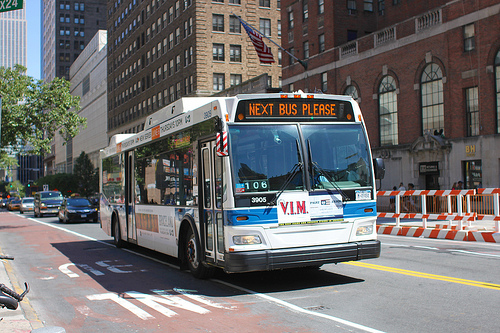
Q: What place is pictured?
A: It is a street.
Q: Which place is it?
A: It is a street.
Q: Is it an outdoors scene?
A: Yes, it is outdoors.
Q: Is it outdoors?
A: Yes, it is outdoors.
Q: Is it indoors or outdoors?
A: It is outdoors.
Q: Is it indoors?
A: No, it is outdoors.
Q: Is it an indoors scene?
A: No, it is outdoors.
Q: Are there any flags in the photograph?
A: Yes, there is a flag.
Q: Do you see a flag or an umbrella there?
A: Yes, there is a flag.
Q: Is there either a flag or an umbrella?
A: Yes, there is a flag.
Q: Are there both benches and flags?
A: No, there is a flag but no benches.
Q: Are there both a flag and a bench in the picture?
A: No, there is a flag but no benches.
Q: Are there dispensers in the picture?
A: No, there are no dispensers.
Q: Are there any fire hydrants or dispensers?
A: No, there are no dispensers or fire hydrants.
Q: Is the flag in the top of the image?
A: Yes, the flag is in the top of the image.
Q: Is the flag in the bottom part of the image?
A: No, the flag is in the top of the image.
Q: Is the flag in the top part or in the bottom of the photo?
A: The flag is in the top of the image.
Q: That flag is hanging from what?
A: The flag is hanging from the building.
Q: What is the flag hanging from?
A: The flag is hanging from the building.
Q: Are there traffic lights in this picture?
A: No, there are no traffic lights.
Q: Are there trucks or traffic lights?
A: No, there are no traffic lights or trucks.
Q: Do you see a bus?
A: Yes, there is a bus.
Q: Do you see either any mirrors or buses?
A: Yes, there is a bus.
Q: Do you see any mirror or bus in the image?
A: Yes, there is a bus.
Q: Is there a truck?
A: No, there are no trucks.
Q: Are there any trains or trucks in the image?
A: No, there are no trucks or trains.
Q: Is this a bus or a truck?
A: This is a bus.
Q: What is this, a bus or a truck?
A: This is a bus.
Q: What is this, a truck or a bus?
A: This is a bus.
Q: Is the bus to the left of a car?
A: No, the bus is to the right of a car.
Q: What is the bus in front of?
A: The bus is in front of the car.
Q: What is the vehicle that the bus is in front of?
A: The vehicle is a car.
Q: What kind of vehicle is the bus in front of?
A: The bus is in front of the car.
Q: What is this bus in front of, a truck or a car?
A: The bus is in front of a car.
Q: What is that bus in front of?
A: The bus is in front of the car.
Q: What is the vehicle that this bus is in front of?
A: The vehicle is a car.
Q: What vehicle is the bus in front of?
A: The bus is in front of the car.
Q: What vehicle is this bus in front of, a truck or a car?
A: The bus is in front of a car.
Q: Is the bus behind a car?
A: No, the bus is in front of a car.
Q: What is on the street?
A: The bus is on the street.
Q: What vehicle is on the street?
A: The vehicle is a bus.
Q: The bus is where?
A: The bus is on the street.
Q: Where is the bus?
A: The bus is on the street.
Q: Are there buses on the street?
A: Yes, there is a bus on the street.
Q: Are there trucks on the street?
A: No, there is a bus on the street.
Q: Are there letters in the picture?
A: Yes, there are letters.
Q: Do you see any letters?
A: Yes, there are letters.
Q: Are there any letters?
A: Yes, there are letters.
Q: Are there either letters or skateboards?
A: Yes, there are letters.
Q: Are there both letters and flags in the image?
A: Yes, there are both letters and flags.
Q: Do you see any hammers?
A: No, there are no hammers.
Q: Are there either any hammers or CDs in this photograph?
A: No, there are no hammers or cds.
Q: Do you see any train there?
A: No, there are no trains.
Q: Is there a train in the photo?
A: No, there are no trains.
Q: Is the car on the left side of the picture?
A: Yes, the car is on the left of the image.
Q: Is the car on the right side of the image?
A: No, the car is on the left of the image.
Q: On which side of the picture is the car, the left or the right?
A: The car is on the left of the image.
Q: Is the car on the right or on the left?
A: The car is on the left of the image.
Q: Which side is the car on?
A: The car is on the left of the image.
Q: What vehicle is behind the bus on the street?
A: The vehicle is a car.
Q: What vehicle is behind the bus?
A: The vehicle is a car.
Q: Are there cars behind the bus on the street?
A: Yes, there is a car behind the bus.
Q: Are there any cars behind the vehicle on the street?
A: Yes, there is a car behind the bus.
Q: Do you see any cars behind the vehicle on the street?
A: Yes, there is a car behind the bus.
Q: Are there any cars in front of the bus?
A: No, the car is behind the bus.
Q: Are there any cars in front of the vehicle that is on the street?
A: No, the car is behind the bus.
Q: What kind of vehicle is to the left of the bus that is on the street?
A: The vehicle is a car.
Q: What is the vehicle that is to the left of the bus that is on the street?
A: The vehicle is a car.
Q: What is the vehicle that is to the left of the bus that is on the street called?
A: The vehicle is a car.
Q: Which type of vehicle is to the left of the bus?
A: The vehicle is a car.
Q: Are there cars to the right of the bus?
A: No, the car is to the left of the bus.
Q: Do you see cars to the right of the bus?
A: No, the car is to the left of the bus.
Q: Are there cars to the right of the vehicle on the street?
A: No, the car is to the left of the bus.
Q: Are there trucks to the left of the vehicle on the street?
A: No, there is a car to the left of the bus.